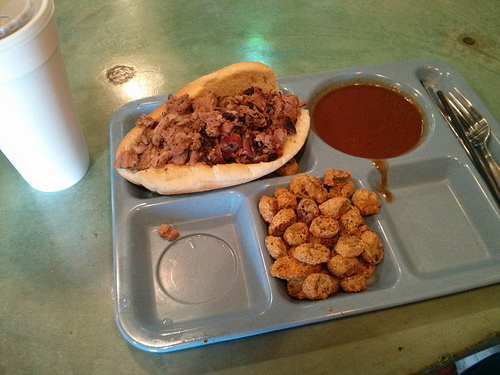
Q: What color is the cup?
A: White.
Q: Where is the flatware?
A: On right.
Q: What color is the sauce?
A: Red.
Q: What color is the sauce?
A: Red.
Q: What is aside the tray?
A: Cup.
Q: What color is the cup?
A: White.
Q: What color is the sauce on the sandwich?
A: Red.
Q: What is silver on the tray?
A: Silverware.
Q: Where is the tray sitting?
A: On a table.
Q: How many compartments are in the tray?
A: Five.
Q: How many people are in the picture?
A: None.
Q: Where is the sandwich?
A: On the tray.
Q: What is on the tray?
A: Sandwich.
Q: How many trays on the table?
A: 1.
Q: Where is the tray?
A: On the table.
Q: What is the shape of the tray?
A: Rectangle.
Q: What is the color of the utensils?
A: Silver.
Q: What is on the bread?
A: Meat.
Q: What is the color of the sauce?
A: Red.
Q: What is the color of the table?
A: Green.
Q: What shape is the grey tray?
A: Rectangle.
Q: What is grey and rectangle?
A: The tray.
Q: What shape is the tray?
A: Rectangle.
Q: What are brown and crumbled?
A: Breadcrumbs.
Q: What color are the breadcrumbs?
A: Brown.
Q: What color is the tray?
A: Blue.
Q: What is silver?
A: Fork.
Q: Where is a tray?
A: On the table.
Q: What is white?
A: Cup.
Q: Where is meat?
A: In a sandwich.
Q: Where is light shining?
A: On the table.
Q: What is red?
A: Ketchup.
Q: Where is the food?
A: In a tray.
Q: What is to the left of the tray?
A: A cup.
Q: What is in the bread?
A: Meat.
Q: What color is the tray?
A: Blue.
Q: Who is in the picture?
A: No one.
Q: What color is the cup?
A: White.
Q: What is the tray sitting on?
A: A table.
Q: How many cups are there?
A: 1.